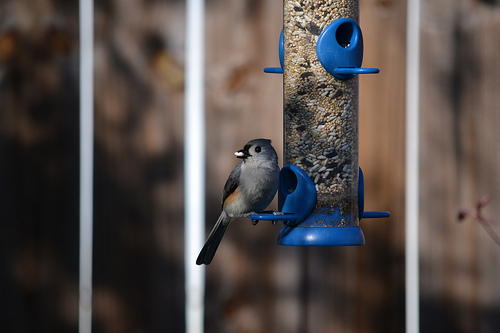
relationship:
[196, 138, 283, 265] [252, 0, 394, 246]
bird on feeder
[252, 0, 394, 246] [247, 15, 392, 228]
feeder has trays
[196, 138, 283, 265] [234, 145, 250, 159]
bird has beak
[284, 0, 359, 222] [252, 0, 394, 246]
seed inside feeder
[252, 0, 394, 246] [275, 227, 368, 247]
feeder has bottom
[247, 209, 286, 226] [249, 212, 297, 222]
feet on perch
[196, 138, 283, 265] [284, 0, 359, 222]
bird eating seed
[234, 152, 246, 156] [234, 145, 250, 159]
seed in beak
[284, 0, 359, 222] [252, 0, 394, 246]
seed in feeder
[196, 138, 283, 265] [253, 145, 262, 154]
bird has eye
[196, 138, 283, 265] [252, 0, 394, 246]
bird sitting on feeder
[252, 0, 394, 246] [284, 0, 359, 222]
feeder filled with seed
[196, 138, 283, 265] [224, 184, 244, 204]
bird has orange patch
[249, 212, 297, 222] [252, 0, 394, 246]
perch on feeder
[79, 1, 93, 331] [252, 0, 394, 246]
pole behind feeder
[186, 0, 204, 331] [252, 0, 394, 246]
pole behind feeder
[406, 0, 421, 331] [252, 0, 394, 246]
pole behind feeder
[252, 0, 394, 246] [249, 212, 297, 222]
feeder has perch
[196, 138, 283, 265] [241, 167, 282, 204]
bird has chest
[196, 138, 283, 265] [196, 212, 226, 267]
bird has tail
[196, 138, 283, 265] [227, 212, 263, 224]
bird has leg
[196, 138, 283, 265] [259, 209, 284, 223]
bird has leg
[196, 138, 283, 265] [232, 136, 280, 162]
bird has head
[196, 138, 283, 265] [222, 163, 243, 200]
bird has wing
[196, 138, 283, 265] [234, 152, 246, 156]
bird has seed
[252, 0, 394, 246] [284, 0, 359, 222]
feeder has seed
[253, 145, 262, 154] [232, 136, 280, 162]
eye on head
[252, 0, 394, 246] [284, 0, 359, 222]
feeder holding seed